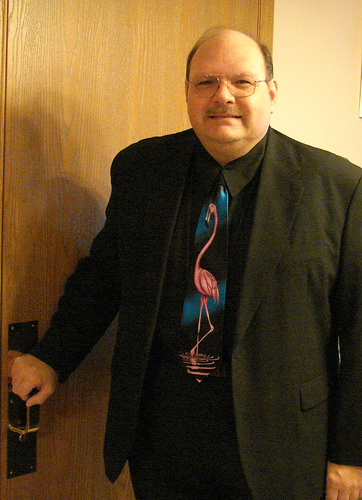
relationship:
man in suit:
[4, 6, 357, 495] [24, 125, 361, 497]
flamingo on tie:
[189, 201, 221, 357] [182, 178, 234, 388]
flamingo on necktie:
[189, 201, 221, 357] [168, 171, 225, 387]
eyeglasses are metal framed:
[187, 71, 267, 97] [184, 74, 267, 96]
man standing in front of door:
[4, 6, 357, 495] [0, 7, 267, 495]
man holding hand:
[10, 23, 362, 499] [12, 350, 58, 408]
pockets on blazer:
[296, 373, 330, 424] [27, 123, 362, 500]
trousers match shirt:
[126, 361, 252, 498] [155, 131, 269, 361]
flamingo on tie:
[189, 201, 221, 357] [175, 182, 230, 388]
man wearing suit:
[4, 6, 357, 495] [24, 125, 361, 497]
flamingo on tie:
[189, 201, 221, 357] [180, 193, 252, 333]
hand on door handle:
[4, 348, 59, 410] [5, 316, 45, 480]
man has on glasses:
[4, 6, 357, 495] [186, 74, 271, 97]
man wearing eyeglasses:
[4, 6, 357, 495] [191, 74, 257, 98]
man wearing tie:
[10, 23, 362, 499] [177, 179, 227, 385]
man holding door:
[10, 23, 362, 499] [8, 2, 233, 496]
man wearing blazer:
[10, 23, 362, 499] [27, 123, 362, 500]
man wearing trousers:
[4, 6, 357, 495] [126, 361, 252, 498]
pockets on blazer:
[298, 378, 332, 433] [78, 123, 333, 497]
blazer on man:
[78, 123, 333, 497] [49, 42, 337, 497]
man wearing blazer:
[4, 6, 357, 495] [24, 126, 361, 498]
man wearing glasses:
[4, 6, 357, 495] [177, 70, 272, 99]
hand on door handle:
[4, 345, 67, 411] [5, 316, 45, 480]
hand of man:
[4, 345, 67, 411] [4, 6, 357, 495]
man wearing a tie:
[4, 6, 357, 495] [185, 165, 243, 391]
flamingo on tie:
[189, 201, 221, 357] [171, 171, 229, 384]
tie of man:
[171, 171, 229, 384] [10, 23, 362, 499]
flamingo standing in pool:
[189, 201, 221, 357] [178, 354, 221, 387]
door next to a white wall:
[0, 7, 267, 495] [276, 5, 356, 151]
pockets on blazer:
[298, 378, 332, 433] [27, 123, 362, 500]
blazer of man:
[27, 123, 362, 500] [4, 6, 357, 495]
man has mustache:
[4, 6, 357, 495] [199, 103, 245, 116]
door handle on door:
[5, 316, 45, 480] [0, 7, 267, 495]